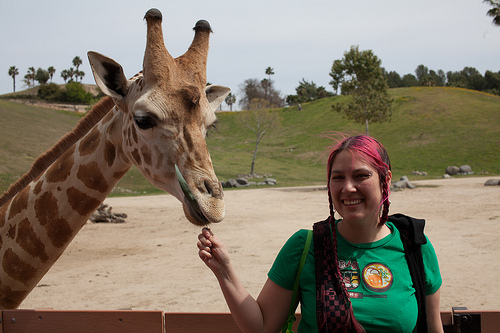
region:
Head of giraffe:
[5, 4, 236, 311]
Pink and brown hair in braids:
[323, 134, 391, 238]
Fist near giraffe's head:
[194, 229, 234, 270]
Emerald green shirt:
[269, 217, 441, 332]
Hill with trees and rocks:
[2, 49, 499, 195]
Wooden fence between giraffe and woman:
[1, 298, 480, 331]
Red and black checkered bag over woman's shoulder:
[313, 213, 366, 331]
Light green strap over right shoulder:
[278, 226, 314, 331]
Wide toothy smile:
[338, 195, 373, 212]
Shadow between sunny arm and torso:
[234, 223, 346, 331]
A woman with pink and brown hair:
[329, 137, 391, 229]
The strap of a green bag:
[296, 228, 314, 296]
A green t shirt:
[273, 226, 437, 330]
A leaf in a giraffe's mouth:
[171, 163, 212, 229]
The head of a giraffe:
[89, 7, 231, 219]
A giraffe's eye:
[132, 105, 165, 133]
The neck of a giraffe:
[1, 109, 128, 313]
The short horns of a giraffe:
[140, 12, 210, 62]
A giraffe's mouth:
[176, 175, 232, 225]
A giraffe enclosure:
[9, 89, 496, 308]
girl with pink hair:
[200, 136, 442, 331]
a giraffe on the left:
[10, 12, 225, 319]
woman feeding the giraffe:
[2, 9, 442, 331]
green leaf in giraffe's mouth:
[173, 164, 209, 226]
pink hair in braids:
[325, 133, 390, 332]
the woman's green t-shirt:
[267, 220, 440, 331]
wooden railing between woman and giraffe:
[4, 310, 498, 331]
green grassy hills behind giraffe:
[0, 82, 497, 187]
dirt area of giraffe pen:
[25, 180, 497, 312]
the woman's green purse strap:
[284, 222, 313, 332]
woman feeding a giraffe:
[0, 11, 456, 328]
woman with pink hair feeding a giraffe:
[5, 5, 495, 326]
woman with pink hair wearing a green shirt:
[218, 122, 458, 328]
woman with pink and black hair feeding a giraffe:
[0, 5, 488, 320]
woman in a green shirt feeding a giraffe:
[20, 4, 487, 331]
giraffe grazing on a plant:
[0, 5, 261, 330]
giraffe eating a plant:
[2, 10, 274, 323]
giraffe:
[5, 3, 275, 328]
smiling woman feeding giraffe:
[10, 11, 490, 311]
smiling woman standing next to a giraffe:
[6, 6, 492, 320]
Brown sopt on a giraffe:
[133, 141, 160, 166]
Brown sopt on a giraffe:
[73, 126, 112, 143]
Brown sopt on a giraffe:
[69, 156, 140, 209]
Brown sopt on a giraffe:
[37, 155, 101, 178]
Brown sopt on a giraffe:
[58, 184, 103, 212]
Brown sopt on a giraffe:
[33, 203, 78, 253]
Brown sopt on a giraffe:
[19, 172, 43, 197]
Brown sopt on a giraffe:
[1, 180, 32, 217]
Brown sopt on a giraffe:
[8, 221, 53, 261]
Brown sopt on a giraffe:
[0, 245, 44, 287]